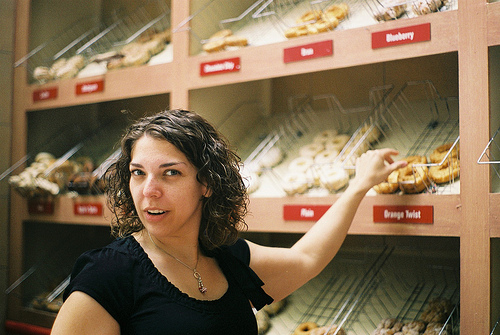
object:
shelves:
[189, 53, 461, 199]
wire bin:
[339, 82, 411, 167]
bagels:
[431, 158, 462, 182]